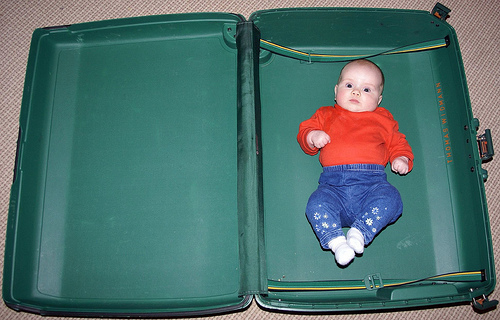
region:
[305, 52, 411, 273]
a baby in orange shirt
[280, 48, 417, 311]
a baby in blue jeans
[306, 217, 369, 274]
a pair of white baby soacks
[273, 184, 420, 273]
jeans with white flowers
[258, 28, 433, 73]
strap on a suit case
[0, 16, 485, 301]
baby in a suitcase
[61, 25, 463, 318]
baby in a green suit case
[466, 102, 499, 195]
handle of a suitcase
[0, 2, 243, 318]
top of a suitcase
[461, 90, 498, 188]
green handle of suitcase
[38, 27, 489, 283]
infant lying in green suitcase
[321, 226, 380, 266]
baby with white socks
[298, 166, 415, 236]
baby wearing blue jeans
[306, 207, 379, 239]
baby's blue jeans have small white flowers on leg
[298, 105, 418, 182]
baby wearing red long sleeved top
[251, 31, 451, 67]
straps to keep items secure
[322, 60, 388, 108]
baby is looking at the camera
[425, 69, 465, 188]
orange writing inside the suitacase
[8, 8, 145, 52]
suitcase on beige carpeting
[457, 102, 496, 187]
lock for the suitcase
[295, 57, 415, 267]
BABY WEARING RED SHIRT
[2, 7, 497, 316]
GREEN SUITCASE OPENED UP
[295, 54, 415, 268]
BABY IN BLUE JEANS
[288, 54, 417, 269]
BABY IN GREEN SUITCASE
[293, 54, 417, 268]
BABY WEARING BLUE JEANS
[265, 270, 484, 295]
GREEN SUITCASE STRAPS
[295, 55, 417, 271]
BABY CLENCHING BOTH HANDS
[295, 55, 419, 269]
THE BABY IS AWAKE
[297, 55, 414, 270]
BABY WEARING WHITE SOCKS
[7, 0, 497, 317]
GREEN SUITCASE ON THE FLOOR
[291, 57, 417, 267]
a baby in a red shirt and jeans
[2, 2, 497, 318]
a green suitcase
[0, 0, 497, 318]
a green suitcase with a baby in it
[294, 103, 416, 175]
a baby's red shirt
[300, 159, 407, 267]
blue jeans with flower pattern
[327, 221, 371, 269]
a pair of white socks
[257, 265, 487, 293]
a green yellow and black luggage strap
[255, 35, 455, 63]
a green black and yellow luggage strap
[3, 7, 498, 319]
an open green suitcase with a baby in it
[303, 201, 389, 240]
a white floral pattern on blue jeans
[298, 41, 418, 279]
baby laying in green suitcase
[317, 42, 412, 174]
baby wearing red shirt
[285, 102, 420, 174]
red shirt is long-sleeved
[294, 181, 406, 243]
blue jeans have white flowers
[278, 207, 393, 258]
baby wearing white socks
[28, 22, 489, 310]
baby in open green suitcase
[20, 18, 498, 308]
green suitcase open on beige rug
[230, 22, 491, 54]
green and yellow striped cord in suitcase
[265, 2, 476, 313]
two green and yellow striped cords